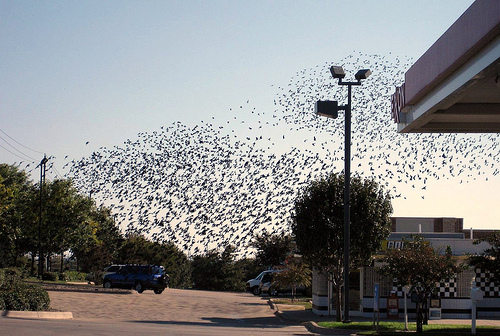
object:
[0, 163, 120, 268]
trees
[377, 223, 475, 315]
wall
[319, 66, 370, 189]
light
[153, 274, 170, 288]
spare tire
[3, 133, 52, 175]
powerlines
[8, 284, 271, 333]
roadway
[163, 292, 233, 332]
street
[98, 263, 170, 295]
suv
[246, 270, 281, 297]
van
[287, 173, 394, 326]
tree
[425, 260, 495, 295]
checks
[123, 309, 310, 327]
shadow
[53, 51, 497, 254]
bird flock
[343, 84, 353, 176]
pole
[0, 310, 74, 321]
median strip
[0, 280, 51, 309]
bushes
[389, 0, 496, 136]
roof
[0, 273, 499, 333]
lot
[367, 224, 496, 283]
building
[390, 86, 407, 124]
letter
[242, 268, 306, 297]
cars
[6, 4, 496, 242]
sky